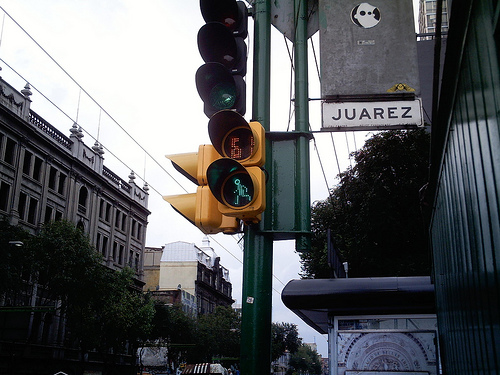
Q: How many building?
A: 3.